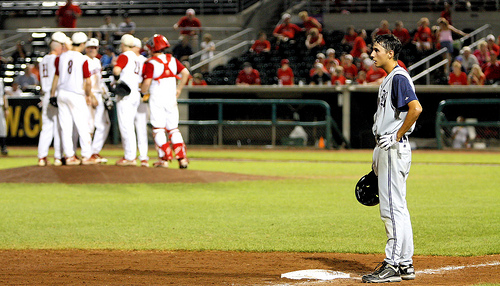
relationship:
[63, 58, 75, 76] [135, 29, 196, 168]
number on player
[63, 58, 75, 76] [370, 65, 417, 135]
number on shirt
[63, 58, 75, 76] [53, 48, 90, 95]
number on shirt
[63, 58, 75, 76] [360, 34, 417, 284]
number on player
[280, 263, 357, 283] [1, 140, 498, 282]
plate on ground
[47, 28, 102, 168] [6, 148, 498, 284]
baseball player on field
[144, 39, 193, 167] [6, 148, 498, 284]
player standing on field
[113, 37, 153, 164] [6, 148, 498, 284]
baseball player standing on field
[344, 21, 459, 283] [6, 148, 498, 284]
player standing on field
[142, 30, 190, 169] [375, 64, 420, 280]
man wearing a uniform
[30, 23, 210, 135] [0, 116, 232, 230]
players standing on mound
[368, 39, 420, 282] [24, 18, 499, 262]
player standing in field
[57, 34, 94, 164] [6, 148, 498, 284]
player standing in field